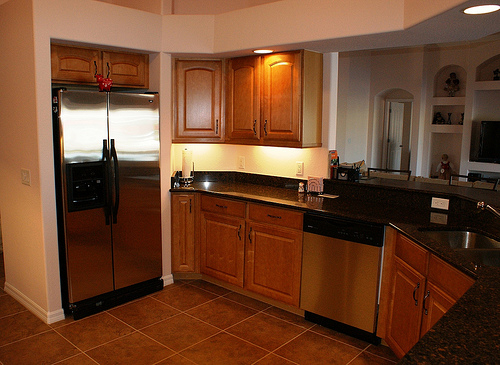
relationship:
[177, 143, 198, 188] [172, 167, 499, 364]
candle on counter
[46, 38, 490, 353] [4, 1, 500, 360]
cabinets in kitchen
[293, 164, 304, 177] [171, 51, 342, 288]
power outlet in wall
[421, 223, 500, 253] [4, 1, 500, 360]
sink in kitchen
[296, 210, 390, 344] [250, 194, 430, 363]
dishwasher between cabinet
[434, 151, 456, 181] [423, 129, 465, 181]
doll on wall shelf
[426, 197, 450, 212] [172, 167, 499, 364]
power outlet on counter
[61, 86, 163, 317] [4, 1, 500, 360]
freezer in kitchen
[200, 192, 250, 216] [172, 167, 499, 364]
drawer under countertop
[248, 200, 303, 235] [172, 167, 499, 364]
drawer under countertop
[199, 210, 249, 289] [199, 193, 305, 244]
cabinet door under drawers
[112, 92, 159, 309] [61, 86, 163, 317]
door on freezer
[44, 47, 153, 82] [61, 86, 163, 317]
cabinets above freezer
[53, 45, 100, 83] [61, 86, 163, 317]
cabinet above freezer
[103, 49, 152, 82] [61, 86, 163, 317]
cabinet above freezer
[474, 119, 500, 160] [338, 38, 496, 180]
entertainment center in wall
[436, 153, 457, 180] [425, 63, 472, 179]
doll on shelves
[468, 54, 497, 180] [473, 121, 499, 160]
shelves beside entertainment center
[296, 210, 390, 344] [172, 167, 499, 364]
dishwasher under counter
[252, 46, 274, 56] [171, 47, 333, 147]
light above cabinets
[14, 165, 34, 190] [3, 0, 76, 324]
light switch on wall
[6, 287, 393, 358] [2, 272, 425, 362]
floor covered in tiles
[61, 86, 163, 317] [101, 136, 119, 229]
freezer ha handles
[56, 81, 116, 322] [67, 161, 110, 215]
door has water maker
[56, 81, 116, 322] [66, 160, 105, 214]
door has ice maker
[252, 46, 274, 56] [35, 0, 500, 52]
light on ceiling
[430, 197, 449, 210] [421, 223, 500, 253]
power outlet by sink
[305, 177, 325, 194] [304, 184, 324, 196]
napkins in holder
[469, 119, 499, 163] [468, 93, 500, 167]
entertainment center on wall shelf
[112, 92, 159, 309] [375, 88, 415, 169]
door in archway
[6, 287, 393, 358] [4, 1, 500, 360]
floor in kitchen